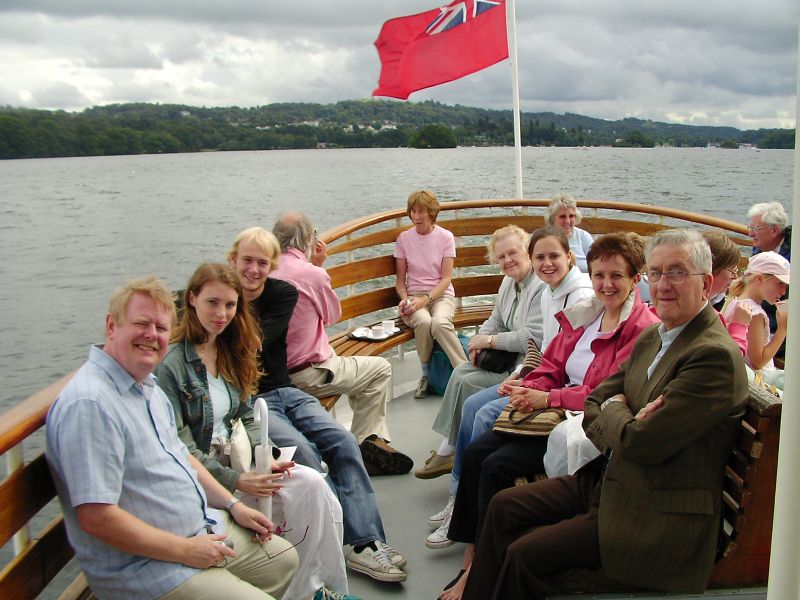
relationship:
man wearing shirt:
[38, 271, 308, 596] [42, 341, 234, 597]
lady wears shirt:
[384, 189, 472, 397] [391, 221, 457, 301]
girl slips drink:
[714, 251, 775, 384] [771, 301, 775, 309]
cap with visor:
[743, 248, 775, 277] [766, 273, 774, 281]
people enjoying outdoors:
[52, 174, 763, 597] [42, 10, 775, 238]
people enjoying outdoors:
[52, 174, 763, 597] [19, 27, 757, 331]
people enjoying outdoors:
[47, 132, 748, 575] [16, 26, 773, 286]